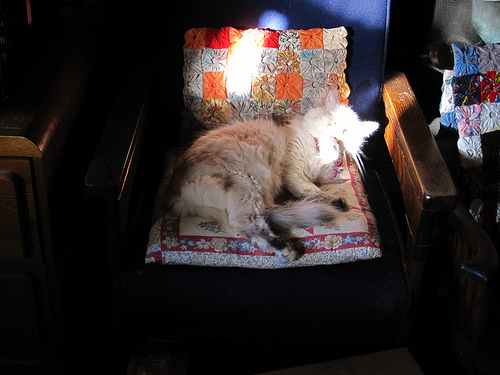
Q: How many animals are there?
A: One.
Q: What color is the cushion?
A: Blue.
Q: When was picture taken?
A: Daytime.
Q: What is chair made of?
A: Wood.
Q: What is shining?
A: Sun ray.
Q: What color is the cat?
A: White.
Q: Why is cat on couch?
A: Nap.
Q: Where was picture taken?
A: In a living room.